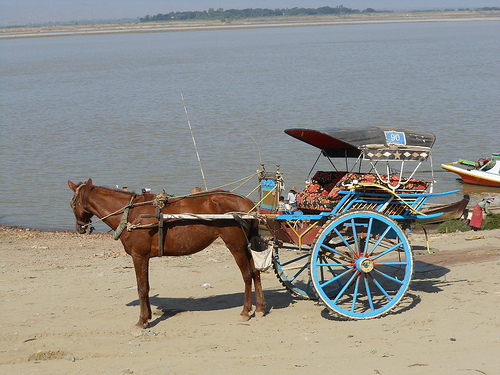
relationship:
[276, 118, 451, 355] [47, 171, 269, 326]
buggy behind horse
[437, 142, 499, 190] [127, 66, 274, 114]
boat on water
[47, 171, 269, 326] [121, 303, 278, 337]
horse has hooves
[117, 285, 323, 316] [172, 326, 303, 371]
shadow on ground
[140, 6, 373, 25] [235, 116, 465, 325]
trees pulls cart